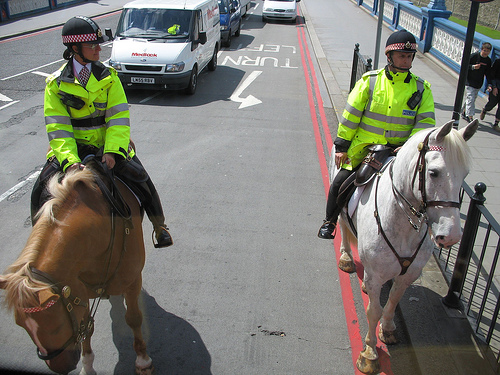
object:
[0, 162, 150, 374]
horse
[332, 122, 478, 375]
horse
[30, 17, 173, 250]
police officer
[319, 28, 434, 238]
police officer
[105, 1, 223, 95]
van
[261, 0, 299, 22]
car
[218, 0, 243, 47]
car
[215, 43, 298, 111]
traffic directions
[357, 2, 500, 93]
wall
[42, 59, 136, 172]
coat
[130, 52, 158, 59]
writing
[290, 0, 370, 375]
stripe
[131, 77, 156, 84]
license plate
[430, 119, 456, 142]
ear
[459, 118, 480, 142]
ear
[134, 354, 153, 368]
ankle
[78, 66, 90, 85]
tie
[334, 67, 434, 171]
jacket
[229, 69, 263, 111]
arrow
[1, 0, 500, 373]
ground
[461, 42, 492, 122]
person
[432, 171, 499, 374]
guardrail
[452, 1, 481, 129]
pole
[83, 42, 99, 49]
eye glasses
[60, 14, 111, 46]
helmet